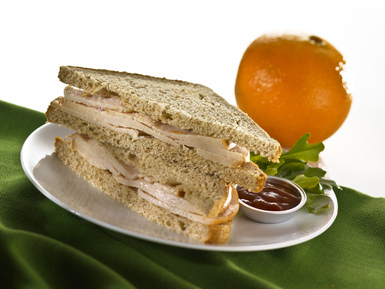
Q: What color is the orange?
A: Orange.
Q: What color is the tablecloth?
A: Green.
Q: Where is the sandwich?
A: On the plate.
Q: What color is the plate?
A: White.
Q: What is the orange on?
A: The table.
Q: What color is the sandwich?
A: Brown and pink.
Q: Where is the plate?
A: On the table.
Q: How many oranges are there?
A: One.